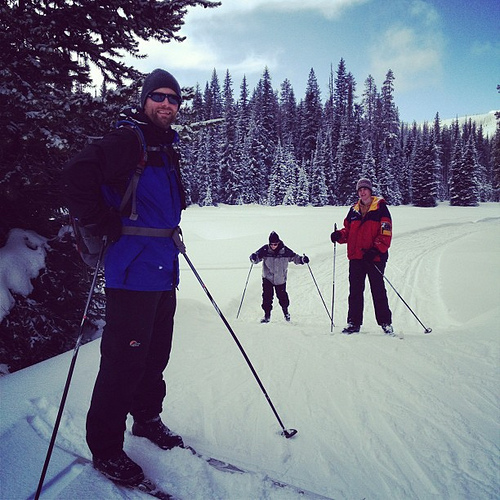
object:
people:
[331, 178, 393, 336]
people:
[249, 230, 309, 324]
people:
[63, 68, 186, 486]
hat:
[141, 68, 182, 110]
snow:
[0, 200, 500, 500]